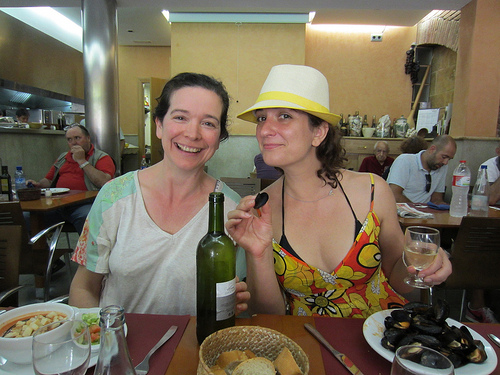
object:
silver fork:
[131, 322, 178, 374]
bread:
[207, 347, 299, 375]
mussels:
[382, 302, 487, 368]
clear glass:
[391, 342, 453, 375]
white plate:
[362, 305, 499, 375]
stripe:
[253, 90, 338, 111]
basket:
[194, 324, 309, 372]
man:
[19, 123, 115, 306]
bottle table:
[195, 190, 236, 348]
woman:
[227, 62, 451, 320]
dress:
[253, 172, 408, 318]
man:
[387, 135, 458, 209]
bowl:
[0, 301, 74, 371]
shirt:
[70, 169, 251, 317]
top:
[98, 303, 129, 327]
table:
[4, 312, 499, 374]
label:
[214, 279, 239, 321]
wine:
[405, 249, 437, 269]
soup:
[0, 311, 64, 339]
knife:
[303, 322, 365, 375]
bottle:
[95, 304, 136, 374]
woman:
[68, 71, 254, 318]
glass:
[401, 223, 441, 291]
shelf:
[342, 135, 404, 156]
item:
[376, 114, 394, 137]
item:
[347, 110, 364, 137]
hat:
[234, 65, 342, 128]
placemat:
[119, 313, 191, 367]